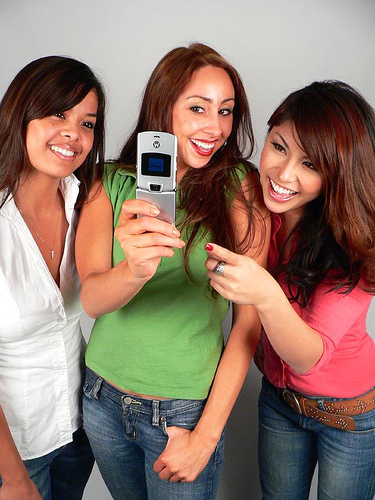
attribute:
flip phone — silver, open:
[133, 130, 180, 236]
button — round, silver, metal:
[152, 140, 160, 148]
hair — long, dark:
[113, 43, 269, 302]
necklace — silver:
[11, 199, 62, 262]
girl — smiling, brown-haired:
[246, 65, 374, 493]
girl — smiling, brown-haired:
[2, 48, 122, 498]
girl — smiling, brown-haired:
[48, 37, 278, 498]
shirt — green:
[90, 148, 255, 424]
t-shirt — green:
[113, 90, 249, 459]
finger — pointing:
[204, 241, 240, 263]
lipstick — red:
[187, 137, 218, 157]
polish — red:
[204, 243, 214, 250]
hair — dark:
[267, 70, 374, 169]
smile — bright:
[190, 136, 219, 156]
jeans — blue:
[258, 375, 359, 497]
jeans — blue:
[82, 370, 223, 499]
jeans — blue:
[5, 425, 95, 499]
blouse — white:
[0, 175, 85, 460]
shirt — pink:
[252, 204, 363, 402]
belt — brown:
[274, 385, 372, 432]